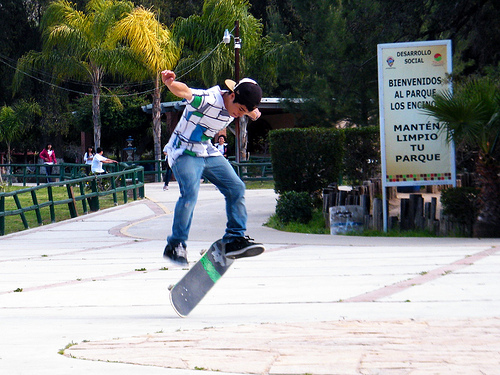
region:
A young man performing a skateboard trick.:
[158, 67, 265, 318]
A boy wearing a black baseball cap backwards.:
[160, 67, 266, 269]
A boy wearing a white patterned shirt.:
[159, 66, 265, 268]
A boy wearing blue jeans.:
[160, 67, 267, 269]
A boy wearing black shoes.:
[158, 68, 265, 266]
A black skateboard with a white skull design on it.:
[167, 235, 237, 315]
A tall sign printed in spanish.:
[375, 39, 457, 233]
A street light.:
[220, 26, 244, 50]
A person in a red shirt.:
[38, 140, 59, 180]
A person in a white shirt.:
[90, 148, 117, 173]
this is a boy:
[130, 61, 283, 255]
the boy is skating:
[128, 58, 288, 265]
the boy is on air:
[133, 65, 283, 263]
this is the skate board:
[175, 261, 212, 301]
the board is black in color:
[189, 264, 205, 286]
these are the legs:
[182, 156, 239, 224]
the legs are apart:
[178, 164, 243, 220]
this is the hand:
[158, 71, 189, 101]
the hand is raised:
[155, 60, 205, 100]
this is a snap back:
[230, 73, 262, 100]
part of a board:
[400, 73, 437, 123]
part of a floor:
[323, 330, 348, 368]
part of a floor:
[365, 265, 382, 293]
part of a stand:
[358, 165, 399, 249]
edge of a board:
[170, 292, 182, 311]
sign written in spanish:
[379, 48, 456, 185]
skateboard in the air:
[179, 235, 233, 322]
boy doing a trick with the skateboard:
[144, 39, 275, 250]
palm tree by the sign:
[439, 78, 496, 220]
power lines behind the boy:
[24, 43, 221, 100]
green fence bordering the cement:
[0, 169, 142, 233]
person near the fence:
[87, 145, 113, 177]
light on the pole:
[216, 18, 242, 50]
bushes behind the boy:
[270, 123, 341, 200]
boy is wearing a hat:
[222, 71, 262, 110]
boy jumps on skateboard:
[156, 59, 275, 328]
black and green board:
[127, 243, 253, 319]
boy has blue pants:
[162, 157, 268, 266]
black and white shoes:
[150, 231, 257, 269]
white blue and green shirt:
[161, 94, 232, 147]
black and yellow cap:
[222, 70, 265, 114]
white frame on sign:
[381, 46, 443, 201]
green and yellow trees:
[42, 0, 267, 89]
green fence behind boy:
[1, 174, 206, 254]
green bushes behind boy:
[263, 120, 378, 212]